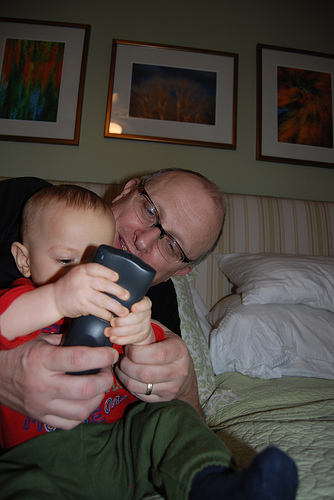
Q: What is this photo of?
A: Man and boy.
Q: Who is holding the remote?
A: Boy.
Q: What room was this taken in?
A: Bedroom.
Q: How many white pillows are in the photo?
A: 2.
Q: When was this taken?
A: Bedtime.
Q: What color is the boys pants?
A: Green.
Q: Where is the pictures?
A: On the wall.